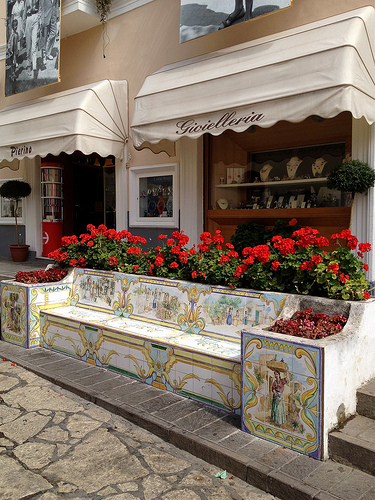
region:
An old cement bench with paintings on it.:
[10, 261, 359, 460]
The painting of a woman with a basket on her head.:
[234, 328, 336, 465]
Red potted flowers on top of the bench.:
[51, 222, 368, 316]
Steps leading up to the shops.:
[294, 375, 373, 499]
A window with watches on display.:
[122, 161, 178, 236]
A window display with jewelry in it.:
[197, 120, 366, 249]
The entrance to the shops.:
[34, 133, 127, 271]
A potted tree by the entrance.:
[2, 172, 37, 265]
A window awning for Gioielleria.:
[134, 7, 374, 167]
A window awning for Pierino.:
[0, 80, 141, 190]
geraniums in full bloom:
[259, 216, 364, 293]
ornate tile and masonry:
[235, 278, 364, 458]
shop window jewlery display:
[203, 141, 332, 233]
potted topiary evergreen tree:
[0, 166, 34, 263]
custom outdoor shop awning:
[0, 70, 129, 164]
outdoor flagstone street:
[22, 393, 67, 431]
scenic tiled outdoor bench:
[93, 270, 228, 392]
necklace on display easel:
[270, 150, 301, 174]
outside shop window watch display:
[126, 165, 171, 217]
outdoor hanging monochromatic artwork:
[1, 0, 68, 96]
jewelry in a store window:
[157, 146, 353, 242]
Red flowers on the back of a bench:
[52, 229, 306, 312]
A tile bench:
[9, 272, 346, 432]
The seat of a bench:
[42, 301, 172, 361]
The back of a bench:
[71, 271, 188, 317]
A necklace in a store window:
[277, 155, 304, 180]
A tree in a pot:
[1, 176, 42, 261]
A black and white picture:
[8, 7, 71, 86]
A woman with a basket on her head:
[259, 353, 311, 427]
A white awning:
[129, 90, 264, 172]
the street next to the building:
[1, 358, 311, 496]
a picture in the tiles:
[240, 332, 317, 455]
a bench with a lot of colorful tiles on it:
[4, 268, 333, 461]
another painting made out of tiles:
[2, 282, 29, 346]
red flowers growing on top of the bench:
[54, 221, 366, 308]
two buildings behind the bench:
[2, 148, 370, 277]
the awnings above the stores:
[5, 8, 373, 127]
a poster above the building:
[4, 1, 63, 88]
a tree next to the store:
[0, 176, 38, 262]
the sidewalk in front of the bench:
[2, 338, 362, 498]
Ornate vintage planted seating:
[14, 226, 367, 390]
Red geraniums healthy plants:
[88, 222, 346, 284]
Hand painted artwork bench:
[0, 275, 257, 358]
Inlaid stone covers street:
[4, 421, 193, 499]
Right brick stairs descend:
[328, 375, 374, 498]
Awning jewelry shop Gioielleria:
[172, 98, 354, 213]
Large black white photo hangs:
[2, 3, 69, 96]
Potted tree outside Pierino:
[4, 139, 35, 269]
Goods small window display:
[124, 161, 188, 232]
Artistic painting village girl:
[254, 347, 311, 432]